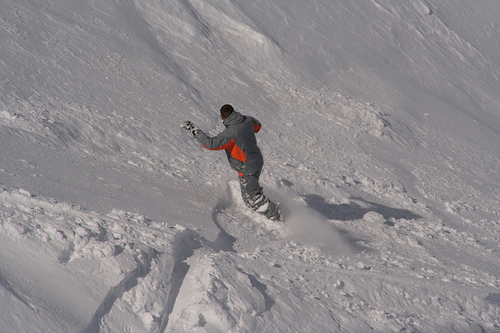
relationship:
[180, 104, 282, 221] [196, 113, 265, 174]
snowboarder wearing jacket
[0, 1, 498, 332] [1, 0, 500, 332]
white snow on mountain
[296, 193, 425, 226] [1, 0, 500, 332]
shade on mountain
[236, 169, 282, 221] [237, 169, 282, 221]
part of trousers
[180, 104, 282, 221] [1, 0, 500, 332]
snowboarder on mountain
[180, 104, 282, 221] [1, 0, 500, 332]
snowboarder going down mountain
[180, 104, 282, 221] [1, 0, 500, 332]
snowboarder riding down mountain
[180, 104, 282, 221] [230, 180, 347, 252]
snowboarder on snowboard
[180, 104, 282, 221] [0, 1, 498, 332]
snowboarder on white snow